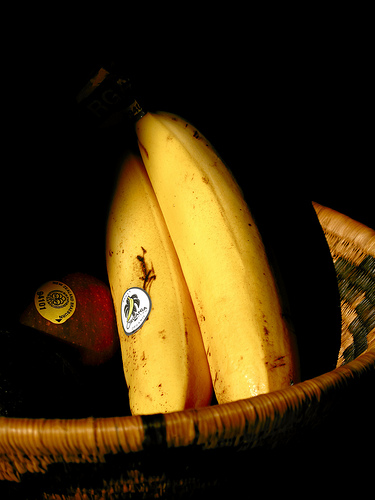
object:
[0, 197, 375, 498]
basket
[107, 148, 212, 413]
banana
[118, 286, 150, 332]
sticker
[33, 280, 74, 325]
sticker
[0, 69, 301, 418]
fruit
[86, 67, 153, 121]
stem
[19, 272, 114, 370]
apple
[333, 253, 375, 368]
markings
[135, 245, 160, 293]
spots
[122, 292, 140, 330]
picture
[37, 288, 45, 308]
number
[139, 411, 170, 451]
stripe